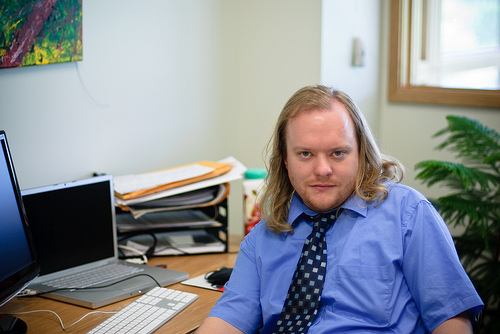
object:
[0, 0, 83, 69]
picture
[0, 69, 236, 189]
wall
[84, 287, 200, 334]
keyborad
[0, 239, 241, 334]
desk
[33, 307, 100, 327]
wooden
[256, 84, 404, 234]
man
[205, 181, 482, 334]
shirt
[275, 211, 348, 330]
blue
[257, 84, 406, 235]
hair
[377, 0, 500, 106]
window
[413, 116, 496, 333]
plant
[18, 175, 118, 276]
monitor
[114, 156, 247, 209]
files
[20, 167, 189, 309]
laptop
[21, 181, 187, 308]
computer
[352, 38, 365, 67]
thermostat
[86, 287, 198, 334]
white